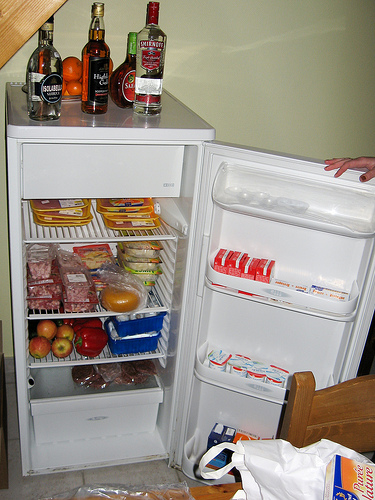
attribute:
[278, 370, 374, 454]
chair — wooden, brown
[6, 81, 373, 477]
fridge — white, small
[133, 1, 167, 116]
bottle — vodka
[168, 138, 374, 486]
door — open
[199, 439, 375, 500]
bag — white